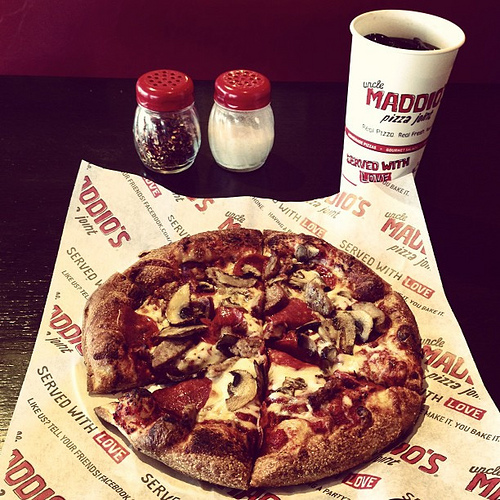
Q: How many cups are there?
A: One.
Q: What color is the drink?
A: Brown.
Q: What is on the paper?
A: A pizza.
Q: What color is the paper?
A: White.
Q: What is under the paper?
A: A table.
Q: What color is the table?
A: Black.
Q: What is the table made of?
A: Wood.